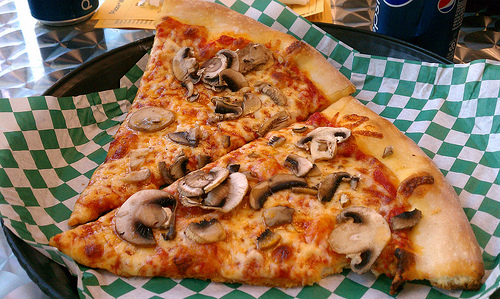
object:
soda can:
[369, 0, 465, 63]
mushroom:
[328, 205, 392, 275]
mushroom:
[111, 187, 179, 247]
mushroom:
[125, 104, 174, 134]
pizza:
[45, 94, 484, 296]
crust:
[317, 93, 486, 292]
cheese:
[45, 112, 416, 295]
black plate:
[0, 21, 500, 299]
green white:
[398, 96, 421, 119]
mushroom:
[111, 188, 175, 248]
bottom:
[24, 0, 102, 28]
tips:
[46, 219, 102, 270]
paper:
[0, 0, 500, 299]